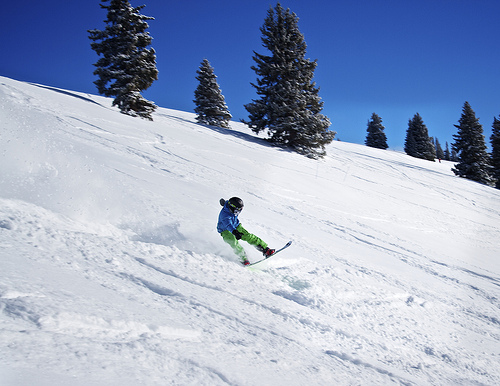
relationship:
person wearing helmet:
[214, 195, 278, 266] [228, 194, 246, 212]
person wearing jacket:
[214, 195, 278, 266] [215, 206, 241, 232]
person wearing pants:
[214, 195, 278, 266] [222, 222, 270, 262]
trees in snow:
[89, 3, 499, 186] [2, 76, 500, 385]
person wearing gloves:
[214, 195, 278, 266] [231, 228, 245, 241]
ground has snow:
[4, 78, 492, 379] [2, 76, 500, 385]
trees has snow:
[89, 3, 499, 186] [94, 3, 500, 186]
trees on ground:
[89, 3, 499, 186] [4, 78, 492, 379]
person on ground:
[214, 195, 278, 266] [4, 78, 492, 379]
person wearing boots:
[214, 195, 278, 266] [242, 247, 277, 268]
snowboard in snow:
[240, 238, 295, 270] [2, 76, 500, 385]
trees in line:
[89, 3, 499, 186] [90, 3, 499, 190]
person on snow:
[214, 195, 278, 266] [2, 76, 500, 385]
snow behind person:
[2, 92, 283, 269] [214, 195, 278, 266]